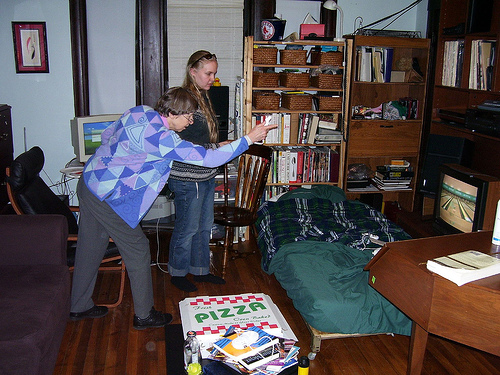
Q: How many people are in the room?
A: Two.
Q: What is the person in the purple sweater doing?
A: Playing video game.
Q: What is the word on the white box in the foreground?
A: Pizza.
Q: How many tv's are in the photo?
A: One.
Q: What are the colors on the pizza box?
A: Red, white and green.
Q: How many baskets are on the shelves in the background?
A: Nine.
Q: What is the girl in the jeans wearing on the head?
A: Sunglasses.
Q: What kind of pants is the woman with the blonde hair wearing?
A: Jeans.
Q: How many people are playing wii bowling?
A: Two.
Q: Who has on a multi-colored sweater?
A: Older lady.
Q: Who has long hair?
A: Younger lady.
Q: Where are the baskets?
A: On shelves.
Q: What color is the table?
A: Brown.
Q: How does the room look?
A: Small and messy.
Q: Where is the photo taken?
A: Bedroom.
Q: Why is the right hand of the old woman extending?
A: Playing wii.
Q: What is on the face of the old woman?
A: Glasses.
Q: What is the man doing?
A: Playing video game.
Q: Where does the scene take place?
A: In a living room.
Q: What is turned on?
A: TV screen.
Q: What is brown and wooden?
A: Floor.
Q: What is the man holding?
A: Game controller.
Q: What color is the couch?
A: Purple.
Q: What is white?
A: Game controller.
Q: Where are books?
A: On shelves.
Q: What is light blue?
A: Wall.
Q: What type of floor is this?
A: Wood.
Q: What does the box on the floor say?
A: Pizza.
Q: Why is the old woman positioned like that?
A: She is playing video games.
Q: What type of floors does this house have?
A: Wood.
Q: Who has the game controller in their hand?
A: The old woman.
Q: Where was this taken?
A: In a living room.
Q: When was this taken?
A: At night.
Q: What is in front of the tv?
A: A cot.